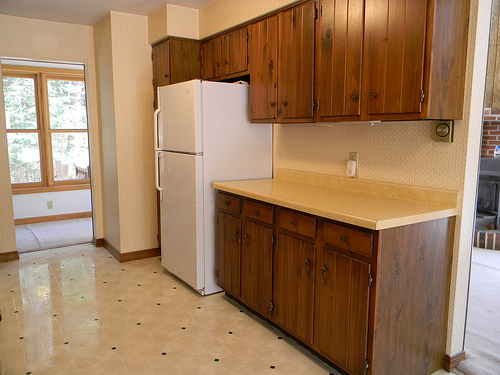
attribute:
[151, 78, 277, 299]
refrigerator — white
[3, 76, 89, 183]
window — large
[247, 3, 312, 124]
cabinet — kitchen, wood, wooden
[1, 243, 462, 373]
floor — linoleum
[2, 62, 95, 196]
frame — white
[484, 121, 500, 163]
wall — brick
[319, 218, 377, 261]
drawer — wooden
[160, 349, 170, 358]
mark — black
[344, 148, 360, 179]
outlet — power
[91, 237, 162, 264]
trimming — wooden